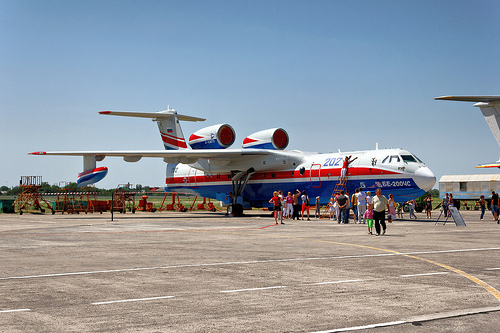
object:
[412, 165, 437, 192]
nose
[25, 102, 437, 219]
plane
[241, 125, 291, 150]
engine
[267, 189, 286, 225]
people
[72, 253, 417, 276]
lines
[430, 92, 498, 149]
tail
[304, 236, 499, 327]
yellowline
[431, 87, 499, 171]
plane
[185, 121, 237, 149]
engine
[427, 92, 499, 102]
wing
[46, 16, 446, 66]
sky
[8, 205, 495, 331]
tarmac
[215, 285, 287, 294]
line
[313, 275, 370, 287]
line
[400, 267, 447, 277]
line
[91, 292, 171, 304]
line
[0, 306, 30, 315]
line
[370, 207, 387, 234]
pants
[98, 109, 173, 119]
wing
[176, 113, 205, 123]
wing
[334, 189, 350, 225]
people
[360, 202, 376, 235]
people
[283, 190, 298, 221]
people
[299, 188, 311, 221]
people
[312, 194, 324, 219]
people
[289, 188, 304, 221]
person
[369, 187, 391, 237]
person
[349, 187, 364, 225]
person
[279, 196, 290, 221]
person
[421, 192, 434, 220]
person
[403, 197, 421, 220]
person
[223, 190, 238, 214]
person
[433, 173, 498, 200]
small building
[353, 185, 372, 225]
person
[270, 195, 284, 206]
shirt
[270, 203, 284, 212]
shorts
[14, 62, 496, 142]
no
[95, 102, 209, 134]
tail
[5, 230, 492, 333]
parts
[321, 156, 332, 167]
numbers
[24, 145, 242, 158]
wing